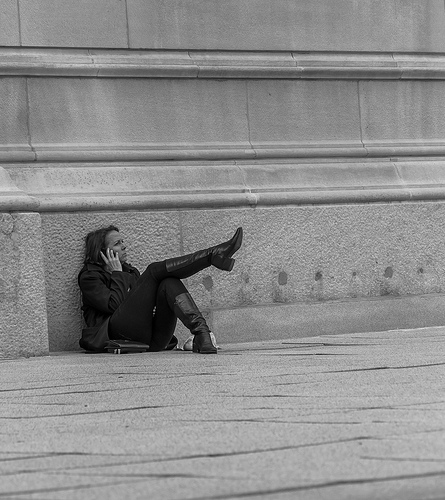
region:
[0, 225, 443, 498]
A woman sitting on the ground.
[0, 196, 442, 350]
A woman leaning against the foundation of a building.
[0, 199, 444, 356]
Concrete building foundation.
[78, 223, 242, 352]
A woman dressed in black.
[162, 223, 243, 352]
Black boots on the woman's feet.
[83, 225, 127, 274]
A woman holding a cell phone next to hear head.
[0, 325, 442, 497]
The ground is paved.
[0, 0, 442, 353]
The side of a concrete building.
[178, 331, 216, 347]
A purse on the ground next to the woman.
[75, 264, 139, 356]
Woman wearing a dark jacket.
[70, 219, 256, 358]
Woman on the ground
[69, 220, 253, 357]
Woman is on the ground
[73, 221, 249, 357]
Woman sitting down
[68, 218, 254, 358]
Woman is sitting down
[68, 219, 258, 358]
Woman sitting down on the ground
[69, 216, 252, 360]
Woman is sitting down on the ground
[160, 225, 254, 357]
Woman wearing boots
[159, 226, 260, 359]
Woman is wearing boots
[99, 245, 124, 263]
Woman is holding a cell phone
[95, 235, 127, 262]
Woman holding a cell phone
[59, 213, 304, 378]
A woman sitting on the sidewalk.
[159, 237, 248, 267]
The woman is wearing black boots.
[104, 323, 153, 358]
The bag is on the ground.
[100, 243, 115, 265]
A woman talking on the cellphone.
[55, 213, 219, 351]
Woman leaning against the wall.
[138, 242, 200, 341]
The woman legs are folded.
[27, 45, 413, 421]
The photo is in black and white.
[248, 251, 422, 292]
Spots on the wall.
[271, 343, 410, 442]
Lines in the ground.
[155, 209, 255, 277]
The boots are tall and black.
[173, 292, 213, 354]
the black boot of the lady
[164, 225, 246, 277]
the black boot of the lady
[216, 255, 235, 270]
the heel of the boot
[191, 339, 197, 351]
the heel of the boot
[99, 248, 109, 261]
the finger of the hand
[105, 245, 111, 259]
the finger of the hand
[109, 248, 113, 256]
the finger of the hand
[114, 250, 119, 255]
the finger of the hand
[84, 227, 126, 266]
the head of the woman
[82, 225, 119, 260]
the hair of the woman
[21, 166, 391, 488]
A person is sitting on the sidewalk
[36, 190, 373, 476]
A person is using their cell phone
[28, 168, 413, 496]
A person is talking to someone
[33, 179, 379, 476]
A person is wearing long dark boots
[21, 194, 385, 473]
The person is a grown female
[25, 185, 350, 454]
The person is on their lunch break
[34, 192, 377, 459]
The person is waiting for someone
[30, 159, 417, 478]
The person is taking a nice rest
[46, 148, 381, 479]
The person is out in the daytime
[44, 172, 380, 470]
The person is enjoying their day